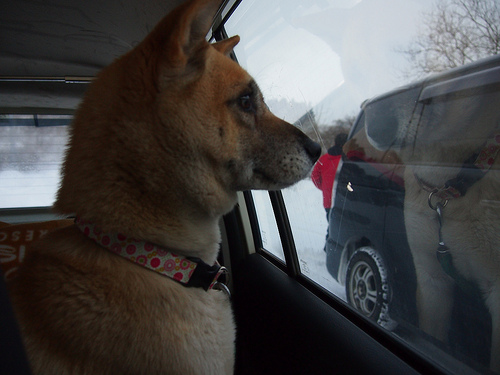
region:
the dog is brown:
[70, 35, 319, 340]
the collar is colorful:
[61, 200, 249, 342]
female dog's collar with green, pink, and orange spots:
[72, 209, 232, 299]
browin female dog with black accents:
[0, 2, 325, 373]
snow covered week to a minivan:
[340, 240, 390, 332]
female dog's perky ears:
[142, 0, 242, 77]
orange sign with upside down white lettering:
[0, 216, 79, 286]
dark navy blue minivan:
[320, 52, 498, 374]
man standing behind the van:
[307, 129, 349, 254]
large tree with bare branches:
[385, 0, 498, 93]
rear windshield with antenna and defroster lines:
[0, 109, 78, 211]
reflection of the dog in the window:
[385, 69, 498, 371]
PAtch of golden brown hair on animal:
[123, 322, 194, 357]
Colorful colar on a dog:
[59, 206, 239, 301]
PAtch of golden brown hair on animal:
[191, 334, 224, 367]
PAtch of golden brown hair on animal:
[198, 296, 227, 330]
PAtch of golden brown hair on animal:
[164, 276, 205, 326]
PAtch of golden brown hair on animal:
[120, 256, 166, 311]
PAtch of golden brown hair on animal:
[57, 232, 116, 275]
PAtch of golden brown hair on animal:
[97, 44, 154, 116]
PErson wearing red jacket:
[310, 119, 365, 263]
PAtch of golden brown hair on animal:
[60, 266, 180, 372]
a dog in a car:
[59, 40, 332, 252]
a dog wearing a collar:
[79, 218, 284, 318]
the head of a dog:
[67, 36, 371, 247]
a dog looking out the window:
[44, 10, 396, 230]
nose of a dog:
[263, 125, 362, 174]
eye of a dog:
[220, 63, 282, 129]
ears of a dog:
[116, 8, 292, 132]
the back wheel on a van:
[317, 60, 467, 313]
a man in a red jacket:
[307, 86, 374, 223]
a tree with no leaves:
[396, 5, 498, 79]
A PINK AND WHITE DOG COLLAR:
[63, 205, 230, 294]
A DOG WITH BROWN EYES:
[188, 65, 323, 191]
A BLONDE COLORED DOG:
[57, 12, 328, 370]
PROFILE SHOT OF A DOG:
[82, 12, 330, 205]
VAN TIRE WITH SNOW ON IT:
[329, 240, 396, 327]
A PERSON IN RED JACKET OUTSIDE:
[314, 123, 336, 242]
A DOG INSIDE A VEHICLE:
[54, 23, 354, 369]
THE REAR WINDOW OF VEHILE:
[8, 106, 70, 220]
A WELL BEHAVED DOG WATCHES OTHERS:
[43, 16, 365, 364]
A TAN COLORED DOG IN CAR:
[65, 26, 343, 256]